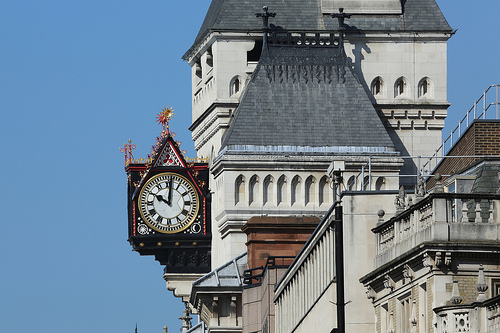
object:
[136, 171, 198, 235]
clock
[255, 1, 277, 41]
cross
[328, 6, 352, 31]
cross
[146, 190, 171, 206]
hand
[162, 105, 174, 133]
decorations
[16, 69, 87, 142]
sky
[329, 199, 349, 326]
pole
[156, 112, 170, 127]
item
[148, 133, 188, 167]
triangle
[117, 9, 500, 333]
building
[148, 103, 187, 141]
top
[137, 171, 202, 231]
ring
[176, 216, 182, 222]
numbers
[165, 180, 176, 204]
arms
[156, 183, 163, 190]
roman numerals